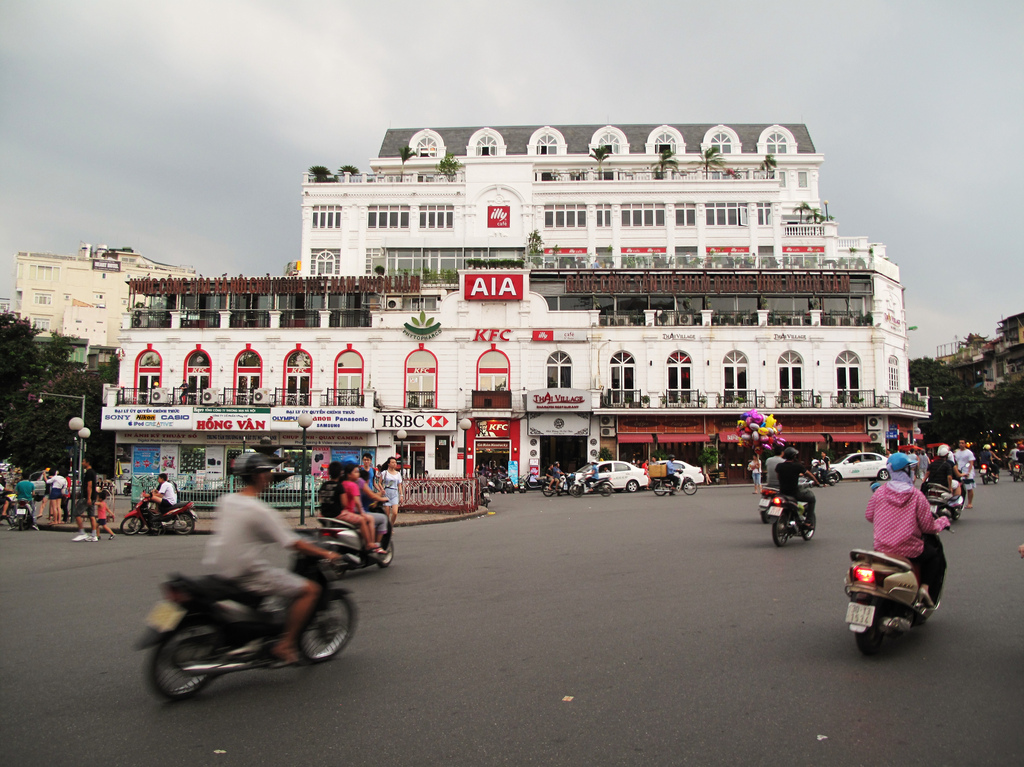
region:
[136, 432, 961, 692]
a group of people that are riding motorized bikes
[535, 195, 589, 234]
windows on a building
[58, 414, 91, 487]
globe lights on a pole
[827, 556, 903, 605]
the rear brake light of a motor scooter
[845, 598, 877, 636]
a white license plate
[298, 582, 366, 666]
the front wheel of a motorcycle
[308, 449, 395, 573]
two people riding on a motor scooter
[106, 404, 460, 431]
signage of various businesses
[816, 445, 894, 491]
a white car on the street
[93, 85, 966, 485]
large white building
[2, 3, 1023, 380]
sky is covered in thick gray clouds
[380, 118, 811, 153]
the roof is gray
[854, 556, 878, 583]
red light on the back of the bike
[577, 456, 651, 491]
small white car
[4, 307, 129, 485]
dark green leaves on the tree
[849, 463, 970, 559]
light purple jacket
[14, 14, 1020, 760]
picture taken outdoors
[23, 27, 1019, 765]
picture taken during the day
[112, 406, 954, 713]
people are riding motorcycles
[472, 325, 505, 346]
a sign says KFC on the building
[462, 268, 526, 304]
the building has the letters AIA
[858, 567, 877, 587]
the light is on the bike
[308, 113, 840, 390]
the building is white and old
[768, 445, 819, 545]
person in black shirt on black bike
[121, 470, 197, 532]
person in white shirt on red bike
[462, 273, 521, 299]
large red sign on huge white building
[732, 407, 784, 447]
big bundle of balloons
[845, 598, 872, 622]
white rear license plate on bike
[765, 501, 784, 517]
white rear license plate on bike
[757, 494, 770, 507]
white rear license plate on far bike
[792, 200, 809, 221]
tall green tree on fifth floor balcony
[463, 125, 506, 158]
large arched window with white trim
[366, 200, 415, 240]
windows on a house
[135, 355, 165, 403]
windows on a house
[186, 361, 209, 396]
windows on a house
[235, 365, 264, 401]
windows on a house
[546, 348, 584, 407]
windows on a house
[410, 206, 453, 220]
windows on a house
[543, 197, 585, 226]
windows on a house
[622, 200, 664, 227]
windows on a house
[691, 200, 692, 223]
windows on a house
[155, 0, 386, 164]
a large white cloud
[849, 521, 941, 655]
the back of a motorcycle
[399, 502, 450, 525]
a small sidewalk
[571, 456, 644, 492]
the side of a white car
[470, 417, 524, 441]
colonial sanders logo over open door to building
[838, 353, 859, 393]
a window on the building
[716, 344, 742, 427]
a window on the building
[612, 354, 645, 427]
a window on the building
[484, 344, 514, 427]
a window on the building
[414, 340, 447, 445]
a window on the building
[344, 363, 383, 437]
a window on the building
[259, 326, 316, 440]
a window on the building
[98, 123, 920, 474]
The white building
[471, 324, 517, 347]
The red KFC sign over the window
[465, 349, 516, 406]
The window over the KFC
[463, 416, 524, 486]
The red doorway to the KFC